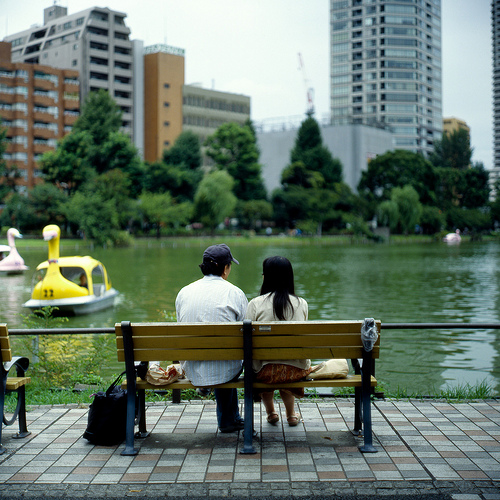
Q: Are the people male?
A: No, they are both male and female.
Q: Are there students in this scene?
A: No, there are no students.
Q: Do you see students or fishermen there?
A: No, there are no students or fishermen.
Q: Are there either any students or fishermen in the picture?
A: No, there are no students or fishermen.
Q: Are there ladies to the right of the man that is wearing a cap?
A: Yes, there is a lady to the right of the man.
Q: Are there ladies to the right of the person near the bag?
A: Yes, there is a lady to the right of the man.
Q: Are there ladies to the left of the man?
A: No, the lady is to the right of the man.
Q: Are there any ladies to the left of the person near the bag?
A: No, the lady is to the right of the man.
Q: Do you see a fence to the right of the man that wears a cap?
A: No, there is a lady to the right of the man.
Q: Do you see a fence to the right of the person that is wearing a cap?
A: No, there is a lady to the right of the man.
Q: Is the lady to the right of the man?
A: Yes, the lady is to the right of the man.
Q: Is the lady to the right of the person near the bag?
A: Yes, the lady is to the right of the man.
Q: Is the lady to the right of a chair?
A: No, the lady is to the right of the man.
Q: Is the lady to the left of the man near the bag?
A: No, the lady is to the right of the man.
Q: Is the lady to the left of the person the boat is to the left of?
A: No, the lady is to the right of the man.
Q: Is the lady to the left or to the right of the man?
A: The lady is to the right of the man.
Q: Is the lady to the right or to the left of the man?
A: The lady is to the right of the man.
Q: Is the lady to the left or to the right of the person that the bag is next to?
A: The lady is to the right of the man.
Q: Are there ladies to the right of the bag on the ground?
A: Yes, there is a lady to the right of the bag.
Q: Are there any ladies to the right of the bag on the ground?
A: Yes, there is a lady to the right of the bag.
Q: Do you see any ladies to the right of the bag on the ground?
A: Yes, there is a lady to the right of the bag.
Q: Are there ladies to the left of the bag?
A: No, the lady is to the right of the bag.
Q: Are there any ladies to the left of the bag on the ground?
A: No, the lady is to the right of the bag.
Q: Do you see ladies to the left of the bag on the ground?
A: No, the lady is to the right of the bag.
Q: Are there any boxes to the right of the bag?
A: No, there is a lady to the right of the bag.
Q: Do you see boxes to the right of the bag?
A: No, there is a lady to the right of the bag.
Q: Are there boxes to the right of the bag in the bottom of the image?
A: No, there is a lady to the right of the bag.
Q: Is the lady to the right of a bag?
A: Yes, the lady is to the right of a bag.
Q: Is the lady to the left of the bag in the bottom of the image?
A: No, the lady is to the right of the bag.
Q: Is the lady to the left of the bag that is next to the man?
A: No, the lady is to the right of the bag.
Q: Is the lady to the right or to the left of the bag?
A: The lady is to the right of the bag.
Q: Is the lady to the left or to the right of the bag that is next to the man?
A: The lady is to the right of the bag.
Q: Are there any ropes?
A: No, there are no ropes.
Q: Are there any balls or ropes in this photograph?
A: No, there are no ropes or balls.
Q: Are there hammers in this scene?
A: No, there are no hammers.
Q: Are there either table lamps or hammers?
A: No, there are no hammers or table lamps.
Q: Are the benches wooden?
A: Yes, the benches are wooden.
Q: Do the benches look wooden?
A: Yes, the benches are wooden.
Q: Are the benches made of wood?
A: Yes, the benches are made of wood.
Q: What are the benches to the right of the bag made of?
A: The benches are made of wood.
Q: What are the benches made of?
A: The benches are made of wood.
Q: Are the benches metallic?
A: No, the benches are wooden.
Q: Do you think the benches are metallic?
A: No, the benches are wooden.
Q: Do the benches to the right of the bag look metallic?
A: No, the benches are wooden.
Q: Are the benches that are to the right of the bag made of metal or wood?
A: The benches are made of wood.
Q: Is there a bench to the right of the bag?
A: Yes, there are benches to the right of the bag.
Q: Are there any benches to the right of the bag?
A: Yes, there are benches to the right of the bag.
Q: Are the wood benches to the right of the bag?
A: Yes, the benches are to the right of the bag.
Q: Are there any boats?
A: Yes, there is a boat.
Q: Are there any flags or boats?
A: Yes, there is a boat.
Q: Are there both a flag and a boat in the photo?
A: No, there is a boat but no flags.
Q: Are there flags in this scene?
A: No, there are no flags.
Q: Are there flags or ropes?
A: No, there are no flags or ropes.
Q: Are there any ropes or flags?
A: No, there are no flags or ropes.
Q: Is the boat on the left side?
A: Yes, the boat is on the left of the image.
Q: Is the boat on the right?
A: No, the boat is on the left of the image.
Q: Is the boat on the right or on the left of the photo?
A: The boat is on the left of the image.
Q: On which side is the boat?
A: The boat is on the left of the image.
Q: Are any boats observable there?
A: Yes, there is a boat.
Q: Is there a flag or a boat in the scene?
A: Yes, there is a boat.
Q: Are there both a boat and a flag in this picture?
A: No, there is a boat but no flags.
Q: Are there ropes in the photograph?
A: No, there are no ropes.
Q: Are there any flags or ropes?
A: No, there are no ropes or flags.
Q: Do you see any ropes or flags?
A: No, there are no ropes or flags.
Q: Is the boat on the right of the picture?
A: No, the boat is on the left of the image.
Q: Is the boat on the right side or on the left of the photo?
A: The boat is on the left of the image.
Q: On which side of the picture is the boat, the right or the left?
A: The boat is on the left of the image.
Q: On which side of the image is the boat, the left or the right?
A: The boat is on the left of the image.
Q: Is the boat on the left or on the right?
A: The boat is on the left of the image.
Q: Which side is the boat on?
A: The boat is on the left of the image.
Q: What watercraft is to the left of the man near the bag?
A: The watercraft is a boat.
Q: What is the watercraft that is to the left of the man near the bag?
A: The watercraft is a boat.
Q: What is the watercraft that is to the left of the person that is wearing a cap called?
A: The watercraft is a boat.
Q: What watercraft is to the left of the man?
A: The watercraft is a boat.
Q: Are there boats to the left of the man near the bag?
A: Yes, there is a boat to the left of the man.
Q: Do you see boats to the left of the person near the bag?
A: Yes, there is a boat to the left of the man.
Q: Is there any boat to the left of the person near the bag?
A: Yes, there is a boat to the left of the man.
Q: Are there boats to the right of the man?
A: No, the boat is to the left of the man.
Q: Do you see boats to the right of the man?
A: No, the boat is to the left of the man.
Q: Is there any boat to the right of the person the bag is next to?
A: No, the boat is to the left of the man.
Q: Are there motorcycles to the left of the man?
A: No, there is a boat to the left of the man.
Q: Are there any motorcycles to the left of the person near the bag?
A: No, there is a boat to the left of the man.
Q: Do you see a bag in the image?
A: Yes, there is a bag.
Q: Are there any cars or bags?
A: Yes, there is a bag.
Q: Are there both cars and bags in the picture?
A: No, there is a bag but no cars.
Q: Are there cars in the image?
A: No, there are no cars.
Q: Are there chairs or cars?
A: No, there are no cars or chairs.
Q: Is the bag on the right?
A: No, the bag is on the left of the image.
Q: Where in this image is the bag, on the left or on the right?
A: The bag is on the left of the image.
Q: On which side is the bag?
A: The bag is on the left of the image.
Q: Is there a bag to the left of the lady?
A: Yes, there is a bag to the left of the lady.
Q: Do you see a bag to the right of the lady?
A: No, the bag is to the left of the lady.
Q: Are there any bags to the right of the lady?
A: No, the bag is to the left of the lady.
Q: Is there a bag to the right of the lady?
A: No, the bag is to the left of the lady.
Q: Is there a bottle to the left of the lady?
A: No, there is a bag to the left of the lady.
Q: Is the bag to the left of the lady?
A: Yes, the bag is to the left of the lady.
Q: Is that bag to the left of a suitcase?
A: No, the bag is to the left of the lady.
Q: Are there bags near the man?
A: Yes, there is a bag near the man.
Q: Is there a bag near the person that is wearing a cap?
A: Yes, there is a bag near the man.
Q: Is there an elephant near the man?
A: No, there is a bag near the man.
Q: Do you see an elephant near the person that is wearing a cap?
A: No, there is a bag near the man.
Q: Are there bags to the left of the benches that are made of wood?
A: Yes, there is a bag to the left of the benches.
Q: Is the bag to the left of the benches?
A: Yes, the bag is to the left of the benches.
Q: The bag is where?
A: The bag is on the ground.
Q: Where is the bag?
A: The bag is on the ground.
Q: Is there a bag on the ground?
A: Yes, there is a bag on the ground.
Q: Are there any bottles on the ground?
A: No, there is a bag on the ground.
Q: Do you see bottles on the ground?
A: No, there is a bag on the ground.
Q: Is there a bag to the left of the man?
A: Yes, there is a bag to the left of the man.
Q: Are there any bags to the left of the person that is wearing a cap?
A: Yes, there is a bag to the left of the man.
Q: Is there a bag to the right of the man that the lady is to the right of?
A: No, the bag is to the left of the man.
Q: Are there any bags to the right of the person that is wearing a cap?
A: No, the bag is to the left of the man.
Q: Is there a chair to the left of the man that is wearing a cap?
A: No, there is a bag to the left of the man.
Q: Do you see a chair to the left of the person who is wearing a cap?
A: No, there is a bag to the left of the man.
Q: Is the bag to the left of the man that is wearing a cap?
A: Yes, the bag is to the left of the man.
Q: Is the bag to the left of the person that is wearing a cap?
A: Yes, the bag is to the left of the man.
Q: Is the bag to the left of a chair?
A: No, the bag is to the left of the man.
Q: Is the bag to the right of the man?
A: No, the bag is to the left of the man.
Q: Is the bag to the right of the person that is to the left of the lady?
A: No, the bag is to the left of the man.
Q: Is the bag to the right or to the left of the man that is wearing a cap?
A: The bag is to the left of the man.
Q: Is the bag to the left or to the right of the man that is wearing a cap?
A: The bag is to the left of the man.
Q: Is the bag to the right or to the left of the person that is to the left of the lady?
A: The bag is to the left of the man.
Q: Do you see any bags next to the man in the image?
A: Yes, there is a bag next to the man.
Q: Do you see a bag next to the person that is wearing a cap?
A: Yes, there is a bag next to the man.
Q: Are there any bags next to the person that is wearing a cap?
A: Yes, there is a bag next to the man.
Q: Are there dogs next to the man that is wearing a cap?
A: No, there is a bag next to the man.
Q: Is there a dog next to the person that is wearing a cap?
A: No, there is a bag next to the man.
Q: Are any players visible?
A: No, there are no players.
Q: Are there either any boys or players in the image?
A: No, there are no players or boys.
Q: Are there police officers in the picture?
A: No, there are no police officers.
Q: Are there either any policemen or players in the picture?
A: No, there are no policemen or players.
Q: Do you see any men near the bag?
A: Yes, there is a man near the bag.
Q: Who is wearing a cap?
A: The man is wearing a cap.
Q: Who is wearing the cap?
A: The man is wearing a cap.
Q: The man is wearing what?
A: The man is wearing a cap.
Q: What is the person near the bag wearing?
A: The man is wearing a cap.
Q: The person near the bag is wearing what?
A: The man is wearing a cap.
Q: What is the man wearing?
A: The man is wearing a cap.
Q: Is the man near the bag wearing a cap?
A: Yes, the man is wearing a cap.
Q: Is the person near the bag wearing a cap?
A: Yes, the man is wearing a cap.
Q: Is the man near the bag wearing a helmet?
A: No, the man is wearing a cap.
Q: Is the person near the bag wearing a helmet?
A: No, the man is wearing a cap.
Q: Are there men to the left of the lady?
A: Yes, there is a man to the left of the lady.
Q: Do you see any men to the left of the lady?
A: Yes, there is a man to the left of the lady.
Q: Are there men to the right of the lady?
A: No, the man is to the left of the lady.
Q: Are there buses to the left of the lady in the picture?
A: No, there is a man to the left of the lady.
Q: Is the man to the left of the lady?
A: Yes, the man is to the left of the lady.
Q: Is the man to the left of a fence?
A: No, the man is to the left of the lady.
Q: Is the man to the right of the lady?
A: No, the man is to the left of the lady.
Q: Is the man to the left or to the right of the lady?
A: The man is to the left of the lady.